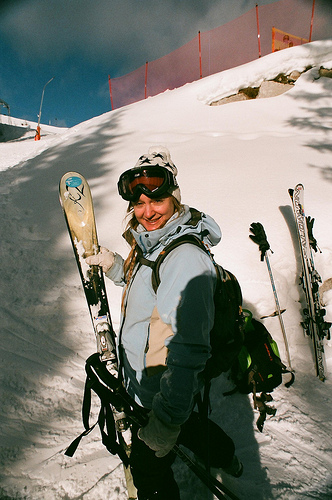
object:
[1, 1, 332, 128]
sky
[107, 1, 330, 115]
fence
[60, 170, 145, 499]
skis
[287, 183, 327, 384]
pole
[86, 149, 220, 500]
woman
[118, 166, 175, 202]
goggles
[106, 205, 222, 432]
top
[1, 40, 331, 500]
ground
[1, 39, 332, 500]
snow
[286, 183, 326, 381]
skis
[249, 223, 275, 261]
gloves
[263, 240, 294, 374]
pole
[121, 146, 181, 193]
hat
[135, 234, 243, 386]
backpack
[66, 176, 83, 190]
circle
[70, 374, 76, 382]
spot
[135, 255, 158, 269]
string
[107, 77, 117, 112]
pole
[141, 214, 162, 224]
grin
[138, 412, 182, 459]
glove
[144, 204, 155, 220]
nose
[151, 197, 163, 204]
eye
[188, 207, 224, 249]
hood